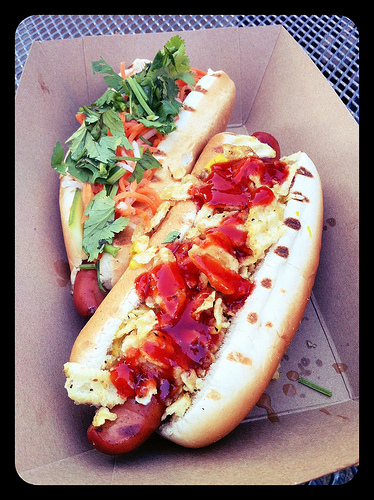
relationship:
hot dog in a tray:
[58, 125, 330, 457] [14, 24, 359, 483]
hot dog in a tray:
[56, 57, 239, 321] [14, 24, 359, 483]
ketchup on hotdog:
[199, 170, 277, 208] [49, 31, 328, 459]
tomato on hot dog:
[212, 168, 275, 205] [58, 125, 330, 457]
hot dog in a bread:
[50, 132, 329, 444] [63, 128, 327, 456]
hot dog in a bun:
[68, 73, 202, 319] [55, 46, 237, 309]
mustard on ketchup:
[197, 141, 289, 185] [204, 155, 293, 186]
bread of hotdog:
[63, 138, 318, 444] [80, 130, 281, 438]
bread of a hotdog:
[63, 128, 327, 456] [87, 395, 165, 455]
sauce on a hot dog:
[155, 268, 178, 291] [58, 125, 330, 457]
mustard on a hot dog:
[124, 253, 145, 272] [50, 132, 329, 444]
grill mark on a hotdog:
[117, 423, 141, 436] [80, 130, 281, 438]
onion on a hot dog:
[130, 138, 144, 157] [56, 57, 239, 321]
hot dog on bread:
[58, 125, 330, 457] [63, 128, 327, 456]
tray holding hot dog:
[32, 73, 361, 409] [58, 125, 330, 457]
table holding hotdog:
[13, 13, 362, 122] [64, 61, 180, 225]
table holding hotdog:
[13, 13, 362, 122] [149, 182, 287, 432]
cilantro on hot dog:
[76, 115, 124, 151] [46, 49, 235, 305]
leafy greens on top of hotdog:
[125, 146, 165, 186] [81, 77, 169, 220]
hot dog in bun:
[56, 57, 239, 321] [55, 59, 231, 318]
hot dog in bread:
[58, 125, 330, 457] [63, 128, 327, 456]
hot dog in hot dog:
[58, 125, 330, 457] [58, 125, 330, 457]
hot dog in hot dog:
[56, 57, 239, 321] [56, 57, 239, 321]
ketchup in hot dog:
[186, 154, 289, 225] [84, 148, 295, 468]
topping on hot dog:
[164, 250, 223, 333] [65, 129, 320, 447]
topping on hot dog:
[100, 69, 159, 158] [62, 54, 236, 311]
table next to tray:
[13, 13, 363, 491] [14, 22, 361, 486]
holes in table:
[31, 15, 90, 36] [13, 13, 363, 491]